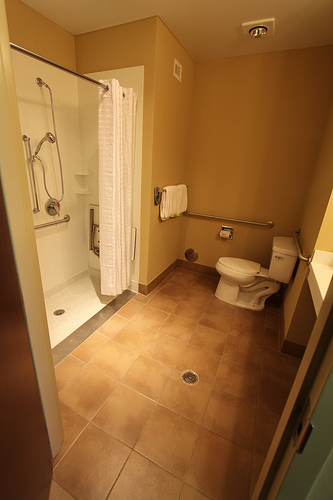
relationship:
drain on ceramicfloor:
[180, 361, 201, 382] [44, 258, 307, 500]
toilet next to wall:
[210, 255, 268, 306] [210, 82, 298, 222]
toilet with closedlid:
[210, 255, 268, 306] [220, 254, 261, 275]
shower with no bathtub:
[18, 48, 121, 329] [52, 243, 129, 312]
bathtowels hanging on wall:
[162, 184, 180, 220] [158, 102, 198, 294]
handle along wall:
[183, 207, 273, 228] [210, 82, 298, 222]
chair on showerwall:
[83, 210, 109, 255] [79, 133, 143, 295]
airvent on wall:
[170, 57, 188, 77] [158, 102, 198, 294]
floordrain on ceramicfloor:
[180, 361, 201, 382] [44, 258, 307, 500]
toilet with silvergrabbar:
[210, 255, 268, 306] [289, 228, 309, 264]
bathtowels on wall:
[162, 184, 180, 220] [158, 102, 198, 294]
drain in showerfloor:
[52, 303, 67, 314] [36, 262, 112, 346]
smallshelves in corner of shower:
[77, 168, 95, 199] [75, 97, 96, 225]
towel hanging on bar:
[159, 184, 191, 220] [160, 187, 194, 197]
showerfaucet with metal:
[34, 101, 58, 162] [34, 134, 55, 153]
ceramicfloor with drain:
[44, 258, 307, 500] [180, 368, 200, 386]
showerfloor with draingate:
[36, 262, 112, 346] [52, 303, 67, 314]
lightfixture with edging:
[241, 21, 294, 55] [249, 26, 269, 38]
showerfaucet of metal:
[34, 101, 58, 162] [34, 134, 55, 153]